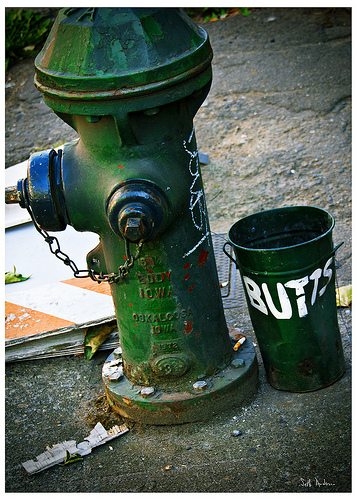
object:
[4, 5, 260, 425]
hydrant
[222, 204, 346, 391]
trash can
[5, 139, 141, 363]
construction stand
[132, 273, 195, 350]
writing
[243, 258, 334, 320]
writing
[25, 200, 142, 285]
chain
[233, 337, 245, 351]
cigarette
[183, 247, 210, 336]
rust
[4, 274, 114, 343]
stripes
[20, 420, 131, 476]
paper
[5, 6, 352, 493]
sidewalk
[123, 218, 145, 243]
bolt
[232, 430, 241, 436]
pebble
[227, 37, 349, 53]
crack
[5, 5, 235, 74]
bush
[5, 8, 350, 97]
background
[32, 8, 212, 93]
top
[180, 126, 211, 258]
chalk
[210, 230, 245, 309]
man hole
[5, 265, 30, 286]
leaves